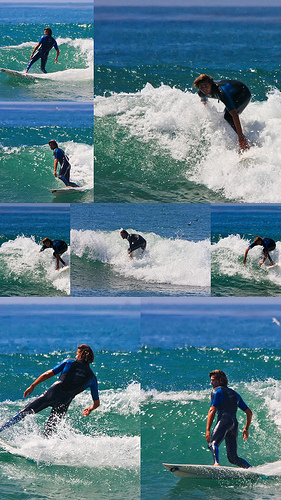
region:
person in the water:
[163, 43, 265, 149]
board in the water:
[154, 453, 263, 487]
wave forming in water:
[146, 403, 192, 449]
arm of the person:
[76, 371, 107, 422]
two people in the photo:
[13, 318, 270, 476]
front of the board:
[149, 448, 201, 489]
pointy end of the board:
[148, 449, 183, 486]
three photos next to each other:
[12, 196, 276, 305]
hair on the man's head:
[67, 341, 104, 369]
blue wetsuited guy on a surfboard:
[7, 327, 128, 463]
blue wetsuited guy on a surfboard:
[152, 358, 263, 475]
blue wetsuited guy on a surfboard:
[231, 222, 275, 274]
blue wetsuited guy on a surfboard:
[103, 217, 165, 265]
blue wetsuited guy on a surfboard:
[26, 223, 66, 275]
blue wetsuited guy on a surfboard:
[182, 49, 254, 154]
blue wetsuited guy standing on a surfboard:
[10, 18, 72, 89]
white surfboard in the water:
[154, 457, 279, 484]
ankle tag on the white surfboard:
[162, 464, 184, 474]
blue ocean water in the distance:
[156, 314, 278, 365]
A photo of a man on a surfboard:
[18, 16, 77, 83]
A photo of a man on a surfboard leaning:
[8, 336, 123, 469]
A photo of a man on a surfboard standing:
[160, 350, 253, 483]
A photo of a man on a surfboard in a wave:
[79, 214, 197, 277]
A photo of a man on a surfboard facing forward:
[221, 222, 273, 281]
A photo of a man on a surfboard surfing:
[35, 127, 81, 200]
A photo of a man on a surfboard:
[160, 64, 265, 157]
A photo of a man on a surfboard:
[35, 135, 85, 198]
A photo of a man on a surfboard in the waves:
[98, 212, 203, 287]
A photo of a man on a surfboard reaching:
[190, 72, 260, 159]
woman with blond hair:
[190, 73, 213, 93]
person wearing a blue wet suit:
[200, 385, 250, 470]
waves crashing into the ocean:
[150, 381, 210, 441]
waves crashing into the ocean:
[94, 388, 140, 470]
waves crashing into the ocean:
[163, 230, 207, 293]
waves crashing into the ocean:
[110, 93, 205, 164]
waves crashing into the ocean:
[64, 35, 96, 99]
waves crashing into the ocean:
[254, 378, 279, 468]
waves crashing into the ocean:
[256, 96, 266, 173]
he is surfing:
[185, 352, 265, 476]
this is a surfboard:
[153, 450, 269, 485]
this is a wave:
[140, 367, 265, 491]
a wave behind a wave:
[142, 334, 272, 379]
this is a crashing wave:
[67, 215, 203, 285]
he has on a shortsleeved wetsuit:
[191, 355, 261, 474]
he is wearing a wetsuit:
[186, 353, 269, 471]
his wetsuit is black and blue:
[186, 357, 261, 465]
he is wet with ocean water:
[167, 358, 271, 461]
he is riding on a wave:
[26, 121, 89, 200]